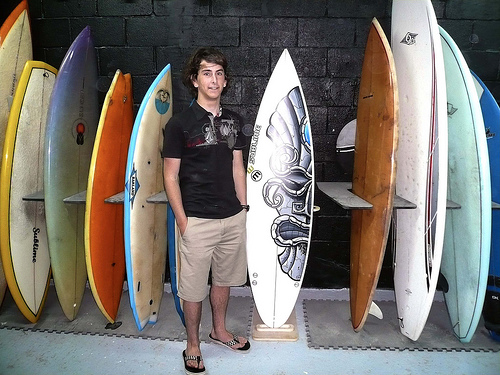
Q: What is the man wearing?
A: Slippers.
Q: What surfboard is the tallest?
A: White one.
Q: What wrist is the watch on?
A: Left.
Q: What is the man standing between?
A: Surfboards.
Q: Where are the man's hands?
A: Pockets.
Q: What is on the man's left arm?
A: Watch.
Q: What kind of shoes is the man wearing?
A: Sandals.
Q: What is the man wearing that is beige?
A: Shorts.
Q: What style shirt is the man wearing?
A: Polo.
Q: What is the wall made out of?
A: Blocks.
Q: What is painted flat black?
A: Wall.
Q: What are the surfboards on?
A: Rack.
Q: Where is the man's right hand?
A: Pocket.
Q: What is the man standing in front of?
A: Surfboard.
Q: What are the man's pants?
A: Shorts.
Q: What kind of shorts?
A: Tan.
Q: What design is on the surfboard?
A: Airbrush.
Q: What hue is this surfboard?
A: Orange.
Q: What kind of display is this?
A: Surfboard.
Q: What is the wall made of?
A: Bricks.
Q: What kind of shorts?
A: Khaki.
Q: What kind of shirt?
A: Short sleeve.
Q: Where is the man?
A: Middle of surfboards.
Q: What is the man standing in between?
A: Surfboards.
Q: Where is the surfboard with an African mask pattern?
A: Middle.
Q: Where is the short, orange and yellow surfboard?
A: Fourth from right.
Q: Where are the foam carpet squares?
A: Floor.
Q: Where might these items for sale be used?
A: Ocean.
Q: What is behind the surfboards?
A: Cinder block wall.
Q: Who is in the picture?
A: A man.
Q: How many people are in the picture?
A: One.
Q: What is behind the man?
A: Surfboards.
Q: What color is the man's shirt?
A: Black.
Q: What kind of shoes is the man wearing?
A: Flip flops.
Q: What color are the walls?
A: Black.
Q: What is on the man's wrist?
A: A watch.